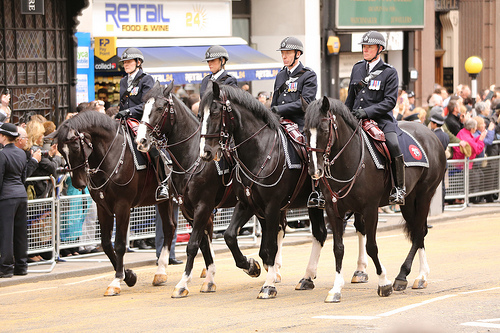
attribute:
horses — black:
[105, 98, 412, 230]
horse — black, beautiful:
[191, 81, 335, 301]